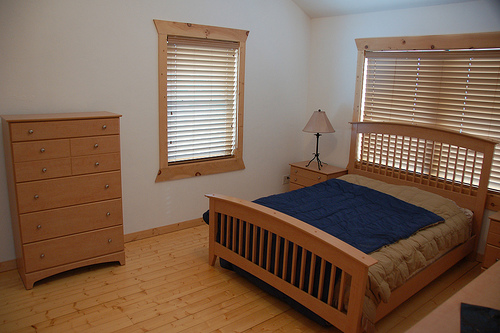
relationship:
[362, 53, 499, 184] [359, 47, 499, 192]
blinds over window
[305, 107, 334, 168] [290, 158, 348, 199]
lamp on night stand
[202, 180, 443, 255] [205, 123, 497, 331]
blanket on bed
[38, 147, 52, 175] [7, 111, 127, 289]
knobs on dresser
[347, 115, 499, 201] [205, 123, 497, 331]
head board of bed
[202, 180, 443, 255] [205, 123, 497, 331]
blanket over bed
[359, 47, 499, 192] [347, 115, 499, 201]
window behind head board